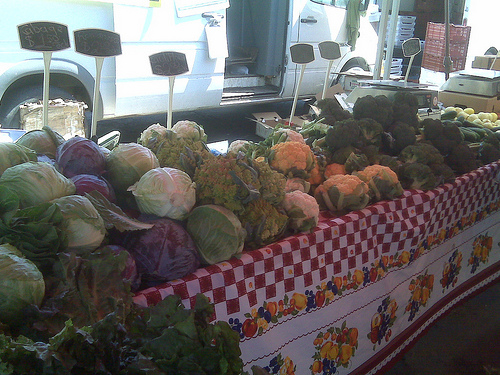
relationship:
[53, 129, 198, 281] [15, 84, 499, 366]
cabbage on table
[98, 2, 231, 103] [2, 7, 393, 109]
door of van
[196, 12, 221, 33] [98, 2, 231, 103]
handle on door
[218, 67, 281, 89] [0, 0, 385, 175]
step in van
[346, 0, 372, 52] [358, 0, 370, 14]
shirt hanging on mirror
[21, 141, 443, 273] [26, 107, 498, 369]
vegetables are on table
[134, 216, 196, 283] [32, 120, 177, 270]
cabbage on bottom stack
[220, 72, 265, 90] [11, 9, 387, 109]
step on truck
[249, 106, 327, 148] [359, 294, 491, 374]
box laying on street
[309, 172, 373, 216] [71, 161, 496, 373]
cauliflower head on table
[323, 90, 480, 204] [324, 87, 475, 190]
pile of broccoli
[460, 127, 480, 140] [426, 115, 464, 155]
cucumber by broccoli